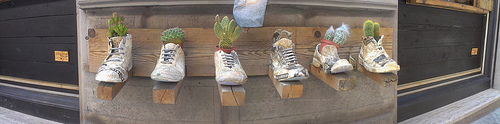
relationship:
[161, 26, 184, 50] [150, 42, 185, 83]
catuses on top of shoe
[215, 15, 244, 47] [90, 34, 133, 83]
catuses on top of shoe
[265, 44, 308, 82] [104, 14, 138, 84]
shoe being used as pots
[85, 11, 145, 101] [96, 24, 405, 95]
cacti growing in sneakers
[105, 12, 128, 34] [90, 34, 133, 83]
cactus growing in shoe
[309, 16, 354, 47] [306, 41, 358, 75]
cactus growing in shoe.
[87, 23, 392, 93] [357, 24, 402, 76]
wall with shoes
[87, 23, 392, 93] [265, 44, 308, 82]
wall with shoe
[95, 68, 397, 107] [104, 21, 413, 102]
wood with shoes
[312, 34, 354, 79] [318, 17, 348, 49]
casual shoe with a cactus